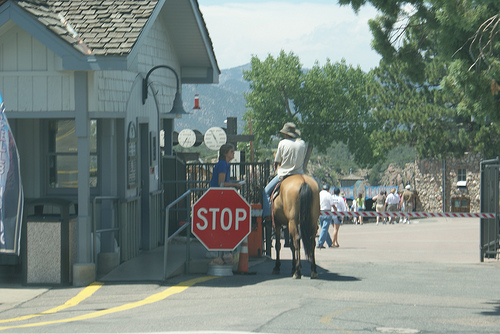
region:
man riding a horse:
[274, 117, 334, 278]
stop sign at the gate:
[194, 180, 251, 253]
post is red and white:
[322, 207, 496, 229]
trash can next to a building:
[18, 188, 86, 294]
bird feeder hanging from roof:
[181, 83, 215, 118]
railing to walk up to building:
[89, 183, 217, 285]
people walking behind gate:
[319, 172, 435, 244]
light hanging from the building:
[135, 61, 199, 121]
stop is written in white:
[193, 202, 247, 231]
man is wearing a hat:
[278, 114, 310, 142]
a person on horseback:
[262, 119, 322, 279]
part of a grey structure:
[0, 4, 220, 283]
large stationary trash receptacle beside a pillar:
[20, 72, 92, 288]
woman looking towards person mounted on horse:
[206, 119, 320, 282]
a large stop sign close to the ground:
[188, 187, 251, 297]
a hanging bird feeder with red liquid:
[189, 68, 201, 111]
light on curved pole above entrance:
[134, 63, 191, 248]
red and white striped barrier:
[320, 210, 498, 217]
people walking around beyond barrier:
[318, 174, 498, 249]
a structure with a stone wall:
[383, 150, 481, 216]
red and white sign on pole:
[182, 166, 259, 238]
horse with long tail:
[281, 175, 333, 284]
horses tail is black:
[290, 178, 325, 278]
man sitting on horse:
[272, 114, 308, 211]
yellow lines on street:
[64, 285, 113, 322]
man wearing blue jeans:
[279, 127, 321, 257]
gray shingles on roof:
[93, 19, 112, 70]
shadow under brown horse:
[304, 250, 350, 302]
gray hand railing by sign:
[168, 191, 185, 262]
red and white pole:
[338, 193, 465, 267]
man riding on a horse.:
[261, 120, 325, 283]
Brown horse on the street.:
[267, 164, 332, 281]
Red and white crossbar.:
[313, 203, 497, 225]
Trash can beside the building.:
[21, 193, 83, 288]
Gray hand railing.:
[160, 185, 197, 270]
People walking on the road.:
[318, 176, 348, 249]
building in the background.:
[0, 0, 222, 277]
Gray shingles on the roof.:
[17, 0, 153, 55]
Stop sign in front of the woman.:
[192, 180, 254, 263]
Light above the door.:
[140, 57, 190, 124]